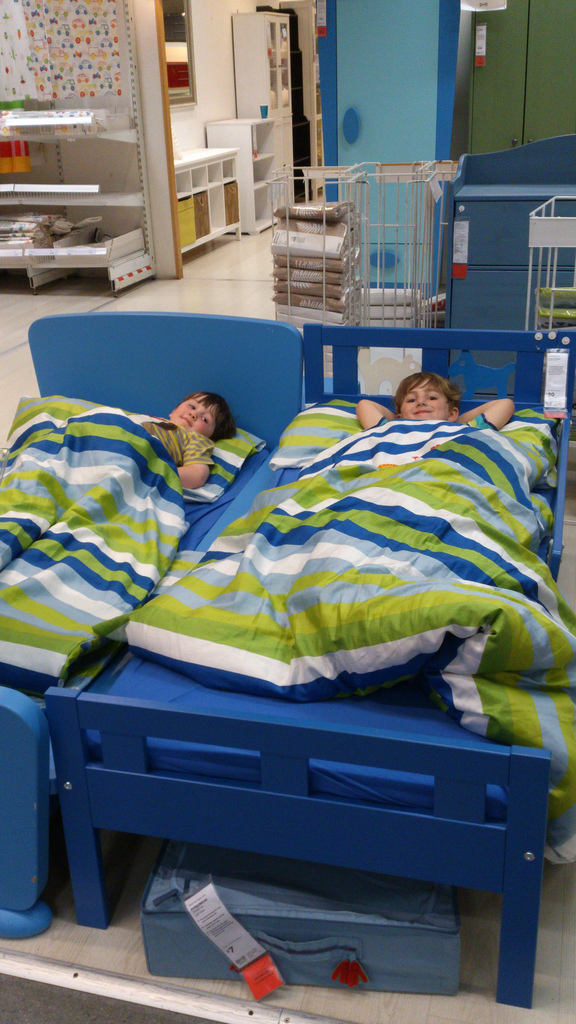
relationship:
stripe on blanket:
[139, 586, 482, 635] [139, 424, 572, 765]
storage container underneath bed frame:
[116, 841, 489, 989] [41, 679, 552, 976]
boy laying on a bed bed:
[351, 368, 519, 449] [50, 321, 570, 857]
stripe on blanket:
[125, 608, 481, 655] [131, 419, 565, 858]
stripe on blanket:
[126, 592, 500, 670] [139, 424, 572, 765]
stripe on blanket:
[196, 543, 529, 596] [98, 415, 562, 698]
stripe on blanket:
[200, 535, 569, 576] [125, 412, 569, 806]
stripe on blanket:
[116, 618, 571, 688] [125, 412, 569, 806]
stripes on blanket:
[180, 414, 541, 636] [139, 403, 576, 779]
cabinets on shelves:
[232, 0, 309, 246] [169, 117, 275, 251]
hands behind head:
[383, 393, 466, 435] [390, 364, 467, 426]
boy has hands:
[351, 369, 519, 449] [383, 393, 466, 435]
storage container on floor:
[139, 835, 462, 998] [0, 859, 571, 1020]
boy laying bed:
[351, 369, 519, 449] [48, 299, 573, 928]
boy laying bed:
[63, 340, 256, 497] [6, 299, 308, 928]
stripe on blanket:
[136, 603, 518, 660] [139, 424, 572, 765]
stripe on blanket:
[231, 495, 528, 548] [125, 412, 569, 806]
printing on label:
[452, 215, 466, 257] [444, 216, 473, 281]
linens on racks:
[272, 201, 342, 329] [260, 159, 456, 330]